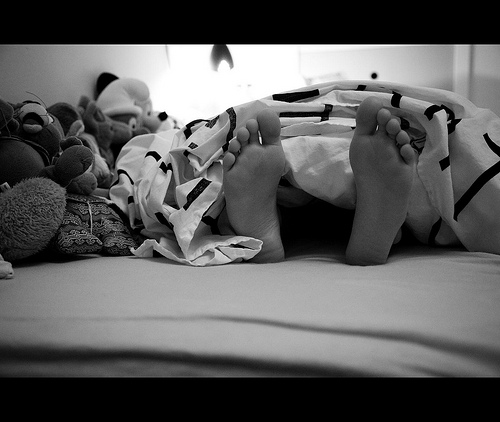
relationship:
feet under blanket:
[202, 90, 389, 259] [282, 91, 326, 148]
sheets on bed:
[109, 287, 130, 298] [28, 352, 79, 377]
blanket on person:
[282, 91, 326, 148] [84, 147, 409, 267]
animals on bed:
[31, 109, 151, 238] [28, 352, 79, 377]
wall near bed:
[48, 63, 65, 69] [28, 352, 79, 377]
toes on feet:
[245, 121, 282, 141] [202, 90, 389, 259]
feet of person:
[202, 90, 389, 259] [84, 147, 409, 267]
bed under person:
[28, 352, 79, 377] [84, 147, 409, 267]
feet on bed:
[202, 90, 389, 259] [28, 352, 79, 377]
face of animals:
[20, 122, 72, 143] [31, 109, 151, 238]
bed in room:
[28, 352, 79, 377] [100, 5, 432, 99]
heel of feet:
[238, 203, 272, 257] [202, 90, 389, 259]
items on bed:
[91, 194, 237, 292] [28, 352, 79, 377]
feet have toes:
[202, 90, 389, 259] [245, 121, 282, 141]